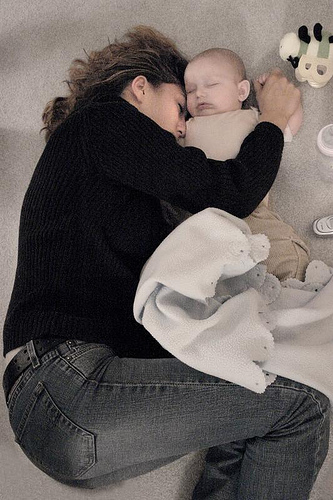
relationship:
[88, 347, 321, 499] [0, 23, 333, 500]
leg of mom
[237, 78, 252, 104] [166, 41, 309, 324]
ear of baby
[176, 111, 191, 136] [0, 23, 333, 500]
nose of mom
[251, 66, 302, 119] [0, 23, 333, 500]
hand of with mom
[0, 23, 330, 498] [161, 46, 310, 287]
mom sleeping with baby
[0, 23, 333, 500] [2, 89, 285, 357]
mom in sweater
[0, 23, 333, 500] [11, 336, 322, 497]
mom in jeans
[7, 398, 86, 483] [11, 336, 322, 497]
pocket on jeans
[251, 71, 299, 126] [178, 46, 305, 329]
hand holding baby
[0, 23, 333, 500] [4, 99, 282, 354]
mom wearing sweater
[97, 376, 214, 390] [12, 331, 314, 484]
stitching on jeans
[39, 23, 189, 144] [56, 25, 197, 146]
hair on head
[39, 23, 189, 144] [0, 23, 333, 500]
hair of mom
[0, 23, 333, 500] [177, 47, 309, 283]
mom sleeping with baby